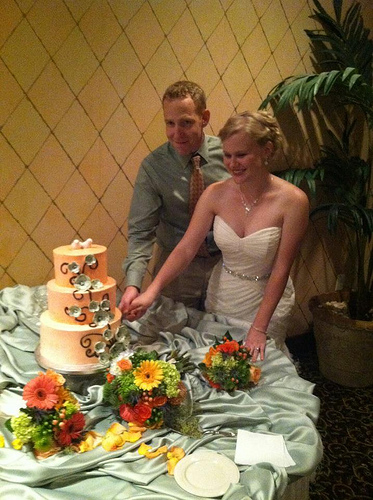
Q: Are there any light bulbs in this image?
A: No, there are no light bulbs.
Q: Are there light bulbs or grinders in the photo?
A: No, there are no light bulbs or grinders.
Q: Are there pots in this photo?
A: Yes, there is a pot.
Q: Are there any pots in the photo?
A: Yes, there is a pot.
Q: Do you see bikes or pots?
A: Yes, there is a pot.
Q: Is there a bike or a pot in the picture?
A: Yes, there is a pot.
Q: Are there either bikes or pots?
A: Yes, there is a pot.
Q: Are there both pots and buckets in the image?
A: No, there is a pot but no buckets.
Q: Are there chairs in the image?
A: No, there are no chairs.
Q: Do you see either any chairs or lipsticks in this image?
A: No, there are no chairs or lipsticks.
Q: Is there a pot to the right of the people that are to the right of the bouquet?
A: Yes, there is a pot to the right of the people.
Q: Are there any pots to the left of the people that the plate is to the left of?
A: No, the pot is to the right of the people.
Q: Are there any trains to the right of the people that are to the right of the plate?
A: No, there is a pot to the right of the people.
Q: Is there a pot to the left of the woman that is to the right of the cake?
A: No, the pot is to the right of the woman.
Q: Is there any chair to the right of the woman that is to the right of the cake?
A: No, there is a pot to the right of the woman.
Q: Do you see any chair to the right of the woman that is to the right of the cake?
A: No, there is a pot to the right of the woman.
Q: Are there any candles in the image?
A: No, there are no candles.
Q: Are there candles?
A: No, there are no candles.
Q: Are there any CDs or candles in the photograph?
A: No, there are no candles or cds.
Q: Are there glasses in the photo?
A: No, there are no glasses.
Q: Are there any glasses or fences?
A: No, there are no glasses or fences.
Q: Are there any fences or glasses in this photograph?
A: No, there are no glasses or fences.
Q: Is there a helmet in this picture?
A: No, there are no helmets.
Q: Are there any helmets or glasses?
A: No, there are no helmets or glasses.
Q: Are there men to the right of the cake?
A: Yes, there is a man to the right of the cake.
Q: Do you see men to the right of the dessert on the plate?
A: Yes, there is a man to the right of the cake.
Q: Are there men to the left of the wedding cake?
A: No, the man is to the right of the cake.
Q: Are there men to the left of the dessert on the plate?
A: No, the man is to the right of the cake.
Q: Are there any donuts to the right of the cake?
A: No, there is a man to the right of the cake.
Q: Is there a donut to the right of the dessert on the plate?
A: No, there is a man to the right of the cake.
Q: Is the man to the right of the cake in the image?
A: Yes, the man is to the right of the cake.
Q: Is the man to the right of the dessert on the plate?
A: Yes, the man is to the right of the cake.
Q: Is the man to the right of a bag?
A: No, the man is to the right of the cake.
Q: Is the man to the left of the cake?
A: No, the man is to the right of the cake.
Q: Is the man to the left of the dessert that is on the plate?
A: No, the man is to the right of the cake.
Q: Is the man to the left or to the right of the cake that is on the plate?
A: The man is to the right of the cake.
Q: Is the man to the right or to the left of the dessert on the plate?
A: The man is to the right of the cake.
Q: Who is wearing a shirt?
A: The man is wearing a shirt.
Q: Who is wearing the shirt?
A: The man is wearing a shirt.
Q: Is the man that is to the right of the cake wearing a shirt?
A: Yes, the man is wearing a shirt.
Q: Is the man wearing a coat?
A: No, the man is wearing a shirt.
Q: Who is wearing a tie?
A: The man is wearing a tie.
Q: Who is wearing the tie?
A: The man is wearing a tie.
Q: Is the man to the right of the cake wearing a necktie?
A: Yes, the man is wearing a necktie.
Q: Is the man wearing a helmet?
A: No, the man is wearing a necktie.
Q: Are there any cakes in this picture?
A: Yes, there is a cake.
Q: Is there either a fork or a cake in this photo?
A: Yes, there is a cake.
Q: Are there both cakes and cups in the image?
A: No, there is a cake but no cups.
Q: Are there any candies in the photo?
A: No, there are no candies.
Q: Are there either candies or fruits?
A: No, there are no candies or fruits.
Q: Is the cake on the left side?
A: Yes, the cake is on the left of the image.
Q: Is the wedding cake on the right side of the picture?
A: No, the cake is on the left of the image.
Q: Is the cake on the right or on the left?
A: The cake is on the left of the image.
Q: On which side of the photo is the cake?
A: The cake is on the left of the image.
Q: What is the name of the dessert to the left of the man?
A: The dessert is a cake.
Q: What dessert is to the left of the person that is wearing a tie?
A: The dessert is a cake.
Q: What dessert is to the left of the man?
A: The dessert is a cake.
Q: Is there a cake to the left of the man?
A: Yes, there is a cake to the left of the man.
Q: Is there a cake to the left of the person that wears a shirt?
A: Yes, there is a cake to the left of the man.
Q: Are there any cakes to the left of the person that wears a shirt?
A: Yes, there is a cake to the left of the man.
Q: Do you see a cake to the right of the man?
A: No, the cake is to the left of the man.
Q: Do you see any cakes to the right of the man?
A: No, the cake is to the left of the man.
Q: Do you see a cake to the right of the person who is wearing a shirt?
A: No, the cake is to the left of the man.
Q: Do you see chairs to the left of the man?
A: No, there is a cake to the left of the man.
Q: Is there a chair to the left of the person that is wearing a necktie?
A: No, there is a cake to the left of the man.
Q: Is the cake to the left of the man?
A: Yes, the cake is to the left of the man.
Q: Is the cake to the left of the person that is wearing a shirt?
A: Yes, the cake is to the left of the man.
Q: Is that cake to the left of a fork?
A: No, the cake is to the left of the man.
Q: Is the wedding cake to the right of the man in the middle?
A: No, the cake is to the left of the man.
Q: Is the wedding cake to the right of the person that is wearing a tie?
A: No, the cake is to the left of the man.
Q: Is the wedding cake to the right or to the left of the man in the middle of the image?
A: The cake is to the left of the man.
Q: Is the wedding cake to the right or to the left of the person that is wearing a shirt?
A: The cake is to the left of the man.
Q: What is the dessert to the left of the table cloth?
A: The dessert is a cake.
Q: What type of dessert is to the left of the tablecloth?
A: The dessert is a cake.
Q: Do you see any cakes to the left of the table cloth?
A: Yes, there is a cake to the left of the table cloth.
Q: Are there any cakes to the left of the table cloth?
A: Yes, there is a cake to the left of the table cloth.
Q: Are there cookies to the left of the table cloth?
A: No, there is a cake to the left of the table cloth.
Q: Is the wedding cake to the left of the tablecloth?
A: Yes, the cake is to the left of the tablecloth.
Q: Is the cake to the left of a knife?
A: No, the cake is to the left of the tablecloth.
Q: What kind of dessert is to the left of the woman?
A: The dessert is a cake.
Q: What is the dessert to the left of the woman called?
A: The dessert is a cake.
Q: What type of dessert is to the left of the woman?
A: The dessert is a cake.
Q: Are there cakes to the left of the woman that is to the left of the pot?
A: Yes, there is a cake to the left of the woman.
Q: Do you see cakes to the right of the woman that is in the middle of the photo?
A: No, the cake is to the left of the woman.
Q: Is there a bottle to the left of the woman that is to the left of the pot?
A: No, there is a cake to the left of the woman.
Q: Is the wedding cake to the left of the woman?
A: Yes, the cake is to the left of the woman.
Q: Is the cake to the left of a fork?
A: No, the cake is to the left of the woman.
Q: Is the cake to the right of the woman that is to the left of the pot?
A: No, the cake is to the left of the woman.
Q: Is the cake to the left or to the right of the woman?
A: The cake is to the left of the woman.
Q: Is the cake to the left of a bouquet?
A: Yes, the cake is to the left of a bouquet.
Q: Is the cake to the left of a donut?
A: No, the cake is to the left of a bouquet.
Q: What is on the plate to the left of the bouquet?
A: The cake is on the plate.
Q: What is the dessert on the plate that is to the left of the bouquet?
A: The dessert is a cake.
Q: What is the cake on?
A: The cake is on the plate.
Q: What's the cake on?
A: The cake is on the plate.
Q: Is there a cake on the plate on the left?
A: Yes, there is a cake on the plate.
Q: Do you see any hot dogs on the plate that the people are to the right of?
A: No, there is a cake on the plate.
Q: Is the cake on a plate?
A: Yes, the cake is on a plate.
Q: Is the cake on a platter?
A: No, the cake is on a plate.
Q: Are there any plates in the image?
A: Yes, there is a plate.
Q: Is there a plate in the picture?
A: Yes, there is a plate.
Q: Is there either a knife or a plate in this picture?
A: Yes, there is a plate.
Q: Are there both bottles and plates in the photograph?
A: No, there is a plate but no bottles.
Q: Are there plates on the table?
A: Yes, there is a plate on the table.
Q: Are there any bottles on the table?
A: No, there is a plate on the table.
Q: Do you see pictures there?
A: No, there are no pictures.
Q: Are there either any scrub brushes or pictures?
A: No, there are no pictures or scrub brushes.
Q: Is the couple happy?
A: Yes, the couple is happy.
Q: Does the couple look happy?
A: Yes, the couple is happy.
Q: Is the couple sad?
A: No, the couple is happy.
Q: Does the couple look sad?
A: No, the couple is happy.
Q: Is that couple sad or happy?
A: The couple is happy.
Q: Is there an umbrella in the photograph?
A: No, there are no umbrellas.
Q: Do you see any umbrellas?
A: No, there are no umbrellas.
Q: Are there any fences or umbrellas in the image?
A: No, there are no umbrellas or fences.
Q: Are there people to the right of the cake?
A: Yes, there are people to the right of the cake.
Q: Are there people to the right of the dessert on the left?
A: Yes, there are people to the right of the cake.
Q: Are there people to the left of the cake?
A: No, the people are to the right of the cake.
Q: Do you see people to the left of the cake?
A: No, the people are to the right of the cake.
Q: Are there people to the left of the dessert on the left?
A: No, the people are to the right of the cake.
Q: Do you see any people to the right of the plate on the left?
A: Yes, there are people to the right of the plate.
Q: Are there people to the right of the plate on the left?
A: Yes, there are people to the right of the plate.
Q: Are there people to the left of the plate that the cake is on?
A: No, the people are to the right of the plate.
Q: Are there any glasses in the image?
A: No, there are no glasses.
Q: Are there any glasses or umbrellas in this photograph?
A: No, there are no glasses or umbrellas.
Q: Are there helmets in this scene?
A: No, there are no helmets.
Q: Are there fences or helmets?
A: No, there are no helmets or fences.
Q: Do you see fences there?
A: No, there are no fences.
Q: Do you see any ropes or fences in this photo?
A: No, there are no fences or ropes.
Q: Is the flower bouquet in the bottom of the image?
A: Yes, the flower bouquet is in the bottom of the image.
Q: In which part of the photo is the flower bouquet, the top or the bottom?
A: The flower bouquet is in the bottom of the image.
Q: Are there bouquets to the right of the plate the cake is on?
A: Yes, there is a bouquet to the right of the plate.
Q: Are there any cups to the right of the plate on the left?
A: No, there is a bouquet to the right of the plate.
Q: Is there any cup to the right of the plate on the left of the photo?
A: No, there is a bouquet to the right of the plate.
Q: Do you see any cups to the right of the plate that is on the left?
A: No, there is a bouquet to the right of the plate.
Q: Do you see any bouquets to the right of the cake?
A: Yes, there is a bouquet to the right of the cake.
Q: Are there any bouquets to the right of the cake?
A: Yes, there is a bouquet to the right of the cake.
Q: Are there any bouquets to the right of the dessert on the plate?
A: Yes, there is a bouquet to the right of the cake.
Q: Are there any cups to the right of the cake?
A: No, there is a bouquet to the right of the cake.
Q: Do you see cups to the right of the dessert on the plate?
A: No, there is a bouquet to the right of the cake.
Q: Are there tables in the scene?
A: Yes, there is a table.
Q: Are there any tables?
A: Yes, there is a table.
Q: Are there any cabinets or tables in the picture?
A: Yes, there is a table.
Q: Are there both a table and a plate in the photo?
A: Yes, there are both a table and a plate.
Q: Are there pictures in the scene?
A: No, there are no pictures.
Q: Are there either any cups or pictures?
A: No, there are no pictures or cups.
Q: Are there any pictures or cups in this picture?
A: No, there are no pictures or cups.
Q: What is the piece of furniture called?
A: The piece of furniture is a table.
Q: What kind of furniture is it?
A: The piece of furniture is a table.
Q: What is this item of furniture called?
A: This is a table.